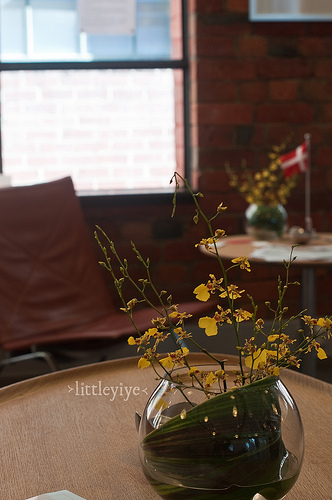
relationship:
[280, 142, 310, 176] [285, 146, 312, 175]
cross with cross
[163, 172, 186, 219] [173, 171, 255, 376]
tip of flower stem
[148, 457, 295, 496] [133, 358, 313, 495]
water in vase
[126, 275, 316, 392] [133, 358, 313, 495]
flowers in vase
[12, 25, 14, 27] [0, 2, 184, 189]
sun in window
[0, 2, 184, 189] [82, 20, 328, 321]
window beside wall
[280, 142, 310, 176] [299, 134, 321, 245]
cross on flagpole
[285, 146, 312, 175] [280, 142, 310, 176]
cross on cross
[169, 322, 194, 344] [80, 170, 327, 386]
flower on plant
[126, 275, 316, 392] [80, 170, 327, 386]
flowers on plant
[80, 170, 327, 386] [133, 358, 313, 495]
plant in vase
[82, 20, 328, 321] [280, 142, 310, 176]
wall near cross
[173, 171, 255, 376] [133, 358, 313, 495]
flower stem in vase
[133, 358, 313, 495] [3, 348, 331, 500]
vase on table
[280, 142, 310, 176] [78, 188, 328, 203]
cross in background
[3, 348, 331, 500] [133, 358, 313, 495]
table next to vase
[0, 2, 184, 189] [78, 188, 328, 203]
window in background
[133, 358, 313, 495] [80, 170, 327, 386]
vase holding plant